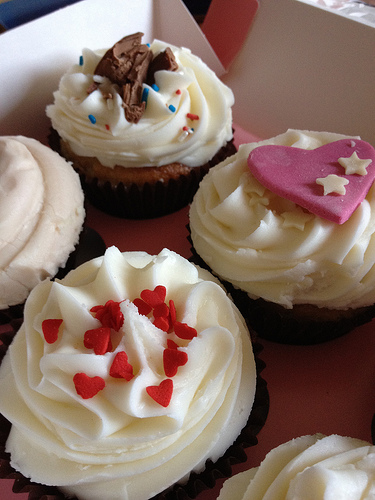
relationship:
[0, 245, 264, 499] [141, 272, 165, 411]
cupcake has red topping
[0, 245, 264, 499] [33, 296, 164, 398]
cupcake has red topping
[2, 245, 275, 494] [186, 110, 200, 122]
cupcake has red topping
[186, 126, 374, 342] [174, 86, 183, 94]
cupcake has red topping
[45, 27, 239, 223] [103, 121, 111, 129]
cupcake has red topping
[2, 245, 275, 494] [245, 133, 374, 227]
cupcake has heart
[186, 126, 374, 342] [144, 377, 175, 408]
cupcake has red topping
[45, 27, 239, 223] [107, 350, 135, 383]
cupcake has red topping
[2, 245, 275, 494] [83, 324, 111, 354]
cupcake has red topping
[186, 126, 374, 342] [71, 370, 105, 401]
cupcake has red topping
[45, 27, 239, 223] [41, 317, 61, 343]
cupcake has red topping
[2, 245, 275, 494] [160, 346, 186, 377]
cupcake has red topping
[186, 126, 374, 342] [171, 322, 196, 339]
cupcake has red topping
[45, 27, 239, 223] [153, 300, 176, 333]
cupcake has red topping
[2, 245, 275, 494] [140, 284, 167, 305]
cupcake has red topping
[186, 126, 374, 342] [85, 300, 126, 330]
cupcake has red topping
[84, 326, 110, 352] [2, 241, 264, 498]
topping on cake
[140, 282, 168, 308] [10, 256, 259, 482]
red topping on cake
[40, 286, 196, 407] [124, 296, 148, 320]
red hearts on cake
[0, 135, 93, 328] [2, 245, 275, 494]
cupcake on cupcake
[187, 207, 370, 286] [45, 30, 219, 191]
icing on cupcake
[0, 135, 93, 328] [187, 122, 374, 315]
cupcake on cupcake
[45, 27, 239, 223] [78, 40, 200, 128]
cupcake has sprinkles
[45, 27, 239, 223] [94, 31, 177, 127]
cupcake has chocolate frosting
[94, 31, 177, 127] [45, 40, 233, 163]
chocolate frosting in middle of vanilla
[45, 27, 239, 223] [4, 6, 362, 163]
cupcake in box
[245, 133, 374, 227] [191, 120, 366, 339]
heart on cupcake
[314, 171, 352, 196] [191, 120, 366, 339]
star on cupcake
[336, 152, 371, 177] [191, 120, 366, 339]
star on cupcake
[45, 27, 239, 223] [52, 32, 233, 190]
cupcake on cupcake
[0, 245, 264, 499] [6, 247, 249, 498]
cupcake on cupcake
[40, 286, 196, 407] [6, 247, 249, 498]
red hearts on cupcake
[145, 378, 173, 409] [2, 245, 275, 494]
sprinkle on cupcake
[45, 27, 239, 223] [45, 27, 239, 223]
cupcake on cupcake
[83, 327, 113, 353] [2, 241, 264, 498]
red topping on cake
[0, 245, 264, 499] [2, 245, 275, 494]
cupcake on cupcake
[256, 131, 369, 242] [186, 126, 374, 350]
heart on cupcake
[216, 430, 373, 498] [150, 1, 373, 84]
cupcake in box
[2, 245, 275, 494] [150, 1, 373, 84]
cupcake in box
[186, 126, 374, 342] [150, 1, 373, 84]
cupcake in box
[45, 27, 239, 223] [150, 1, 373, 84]
cupcake in box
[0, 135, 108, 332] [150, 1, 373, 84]
cupcake in box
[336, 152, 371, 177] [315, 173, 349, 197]
star on a star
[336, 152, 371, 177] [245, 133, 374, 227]
star on a heart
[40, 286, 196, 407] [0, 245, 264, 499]
red hearts on top of cupcake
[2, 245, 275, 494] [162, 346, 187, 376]
cupcake with heart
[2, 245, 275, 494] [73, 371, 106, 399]
cupcake with heart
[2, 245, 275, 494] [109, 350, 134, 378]
cupcake with heart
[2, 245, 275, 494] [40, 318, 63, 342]
cupcake with heart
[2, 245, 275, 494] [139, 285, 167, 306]
cupcake with heart